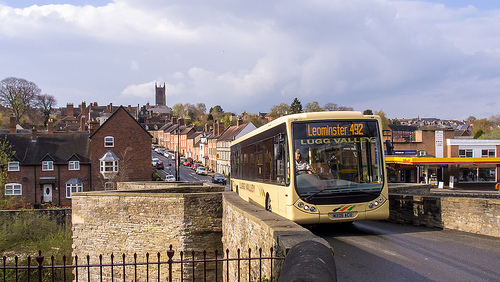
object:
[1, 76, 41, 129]
tree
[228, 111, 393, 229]
bus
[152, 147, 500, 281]
road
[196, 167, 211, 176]
car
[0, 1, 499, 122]
sky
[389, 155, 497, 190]
station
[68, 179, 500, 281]
bridge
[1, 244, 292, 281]
fence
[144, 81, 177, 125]
church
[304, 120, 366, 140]
placard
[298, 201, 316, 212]
light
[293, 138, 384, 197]
windshield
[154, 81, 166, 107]
steeple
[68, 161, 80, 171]
window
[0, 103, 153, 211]
building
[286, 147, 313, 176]
man